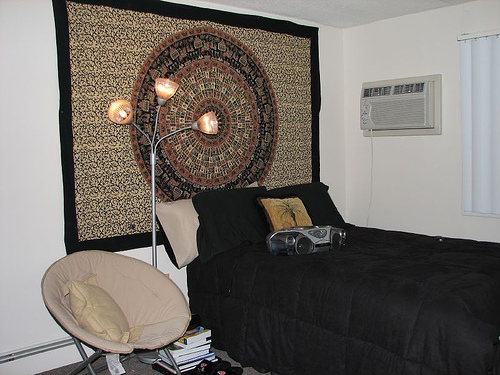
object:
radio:
[262, 220, 346, 257]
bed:
[155, 184, 498, 374]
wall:
[341, 1, 499, 239]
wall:
[1, 2, 336, 348]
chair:
[42, 246, 194, 374]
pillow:
[153, 179, 257, 269]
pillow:
[267, 180, 348, 232]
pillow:
[256, 194, 314, 232]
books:
[184, 332, 215, 344]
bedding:
[188, 178, 499, 373]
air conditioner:
[357, 76, 442, 141]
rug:
[50, 0, 321, 255]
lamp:
[104, 73, 219, 361]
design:
[127, 24, 278, 203]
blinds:
[455, 28, 497, 215]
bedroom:
[1, 1, 499, 374]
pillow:
[62, 274, 134, 344]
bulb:
[118, 107, 130, 119]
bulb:
[208, 118, 216, 131]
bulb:
[159, 80, 171, 97]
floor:
[32, 335, 218, 374]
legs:
[65, 330, 103, 374]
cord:
[360, 127, 376, 228]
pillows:
[192, 185, 265, 269]